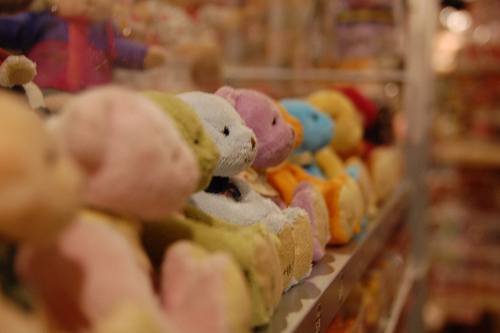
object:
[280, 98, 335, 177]
blue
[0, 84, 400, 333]
teddy bear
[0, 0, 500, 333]
toy shop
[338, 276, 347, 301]
shelf sticker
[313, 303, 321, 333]
shelf sticker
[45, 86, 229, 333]
stuffed animal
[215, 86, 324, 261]
stuffed toy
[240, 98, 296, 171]
face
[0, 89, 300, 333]
teddy bear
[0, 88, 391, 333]
animal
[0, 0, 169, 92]
animal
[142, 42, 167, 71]
paw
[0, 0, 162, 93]
teddy bear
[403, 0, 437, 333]
metal bar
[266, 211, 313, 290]
foot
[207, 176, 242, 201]
tie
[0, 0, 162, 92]
doll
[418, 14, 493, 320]
area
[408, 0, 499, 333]
entrance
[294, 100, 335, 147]
face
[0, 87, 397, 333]
toys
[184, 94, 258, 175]
bear face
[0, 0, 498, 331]
shelves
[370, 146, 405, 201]
feet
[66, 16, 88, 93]
suspenders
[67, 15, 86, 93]
tie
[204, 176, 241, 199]
scarf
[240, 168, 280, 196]
jacket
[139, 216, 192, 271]
jacket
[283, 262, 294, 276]
letter